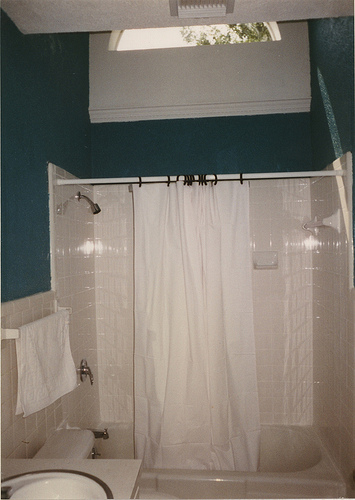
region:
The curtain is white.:
[131, 182, 258, 467]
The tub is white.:
[77, 418, 345, 491]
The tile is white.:
[315, 189, 346, 441]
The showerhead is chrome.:
[77, 187, 105, 220]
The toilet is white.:
[51, 426, 110, 460]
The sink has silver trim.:
[5, 461, 125, 498]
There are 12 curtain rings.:
[137, 175, 253, 187]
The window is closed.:
[112, 25, 276, 50]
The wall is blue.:
[12, 79, 39, 268]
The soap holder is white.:
[253, 250, 280, 268]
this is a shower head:
[70, 186, 111, 224]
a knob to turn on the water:
[72, 352, 102, 390]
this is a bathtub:
[78, 413, 348, 486]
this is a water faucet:
[81, 418, 123, 443]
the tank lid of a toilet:
[36, 421, 105, 465]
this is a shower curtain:
[120, 179, 273, 477]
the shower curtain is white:
[126, 175, 278, 480]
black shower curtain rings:
[126, 169, 255, 196]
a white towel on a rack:
[8, 291, 93, 424]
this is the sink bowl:
[11, 471, 109, 498]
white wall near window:
[94, 10, 317, 121]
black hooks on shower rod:
[124, 165, 245, 197]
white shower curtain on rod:
[144, 198, 242, 453]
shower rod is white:
[60, 178, 354, 185]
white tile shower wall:
[279, 210, 311, 260]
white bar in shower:
[289, 218, 347, 245]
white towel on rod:
[9, 280, 64, 437]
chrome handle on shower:
[76, 347, 103, 389]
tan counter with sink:
[2, 448, 151, 480]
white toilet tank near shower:
[30, 424, 96, 461]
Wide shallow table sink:
[25, 471, 108, 495]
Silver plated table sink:
[35, 468, 90, 475]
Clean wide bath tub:
[269, 429, 308, 471]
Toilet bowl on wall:
[47, 435, 90, 451]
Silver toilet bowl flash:
[90, 446, 103, 457]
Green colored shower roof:
[109, 141, 236, 160]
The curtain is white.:
[131, 182, 266, 468]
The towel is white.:
[12, 309, 90, 411]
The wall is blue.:
[3, 105, 37, 271]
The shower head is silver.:
[74, 186, 99, 215]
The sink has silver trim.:
[2, 459, 116, 499]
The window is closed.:
[106, 26, 286, 51]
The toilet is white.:
[31, 422, 99, 461]